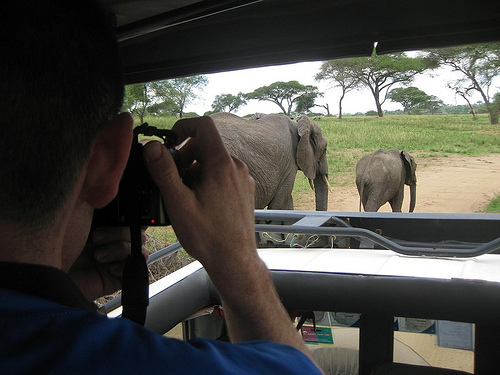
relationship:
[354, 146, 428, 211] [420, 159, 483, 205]
elephant walking on dirt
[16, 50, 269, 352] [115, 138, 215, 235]
person holding camera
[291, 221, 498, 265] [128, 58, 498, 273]
bar attached to window